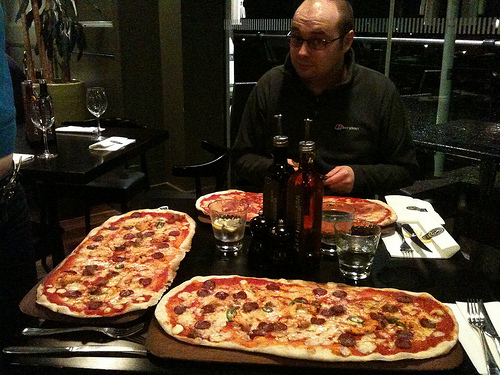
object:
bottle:
[284, 114, 325, 267]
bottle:
[258, 111, 296, 237]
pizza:
[192, 185, 400, 237]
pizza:
[32, 203, 201, 322]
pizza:
[147, 271, 463, 368]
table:
[1, 193, 499, 375]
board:
[195, 206, 398, 240]